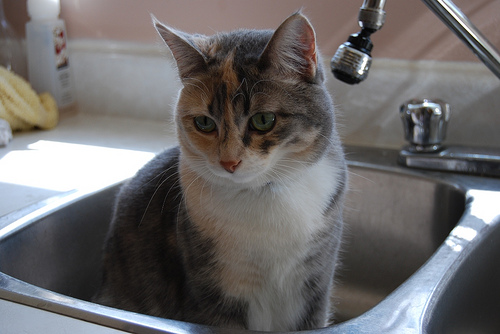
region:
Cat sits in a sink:
[108, 6, 366, 328]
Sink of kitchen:
[11, 130, 481, 330]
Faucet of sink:
[324, 0, 497, 105]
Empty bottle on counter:
[14, 0, 95, 114]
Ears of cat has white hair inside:
[146, 7, 330, 101]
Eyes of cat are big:
[168, 101, 284, 142]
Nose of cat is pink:
[211, 151, 245, 178]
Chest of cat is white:
[206, 171, 318, 311]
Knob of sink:
[390, 76, 465, 171]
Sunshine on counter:
[6, 129, 163, 206]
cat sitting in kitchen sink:
[132, 10, 448, 326]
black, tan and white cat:
[100, 19, 395, 331]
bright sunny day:
[0, 18, 170, 254]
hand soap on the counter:
[20, 0, 97, 108]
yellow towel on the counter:
[3, 55, 59, 162]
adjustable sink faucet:
[320, 13, 405, 103]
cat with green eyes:
[152, 88, 328, 150]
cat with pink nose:
[215, 155, 246, 187]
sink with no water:
[355, 95, 445, 328]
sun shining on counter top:
[8, 121, 128, 203]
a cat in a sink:
[93, 9, 396, 331]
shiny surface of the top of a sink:
[5, 110, 150, 222]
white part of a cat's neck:
[196, 162, 338, 277]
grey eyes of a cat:
[184, 106, 276, 133]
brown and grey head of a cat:
[156, 15, 338, 177]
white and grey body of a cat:
[104, 156, 339, 332]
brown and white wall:
[63, 4, 160, 124]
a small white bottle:
[27, 2, 64, 103]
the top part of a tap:
[331, 5, 381, 92]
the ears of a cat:
[156, 8, 332, 85]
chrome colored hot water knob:
[397, 96, 454, 149]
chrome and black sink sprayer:
[330, 25, 376, 85]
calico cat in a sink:
[94, 5, 353, 328]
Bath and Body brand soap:
[22, 1, 81, 118]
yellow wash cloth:
[0, 63, 59, 134]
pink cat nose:
[217, 157, 243, 173]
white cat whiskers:
[139, 155, 371, 222]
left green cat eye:
[245, 109, 281, 134]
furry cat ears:
[149, 7, 320, 82]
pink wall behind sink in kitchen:
[3, 3, 498, 66]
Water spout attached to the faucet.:
[335, 16, 380, 87]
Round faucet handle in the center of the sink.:
[390, 85, 450, 150]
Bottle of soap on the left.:
[20, 0, 80, 120]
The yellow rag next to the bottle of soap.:
[0, 62, 57, 136]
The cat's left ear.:
[145, 11, 205, 71]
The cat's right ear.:
[256, 15, 321, 80]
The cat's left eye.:
[185, 106, 220, 136]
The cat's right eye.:
[245, 105, 275, 135]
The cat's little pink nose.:
[215, 150, 242, 175]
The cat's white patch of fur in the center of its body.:
[173, 157, 344, 329]